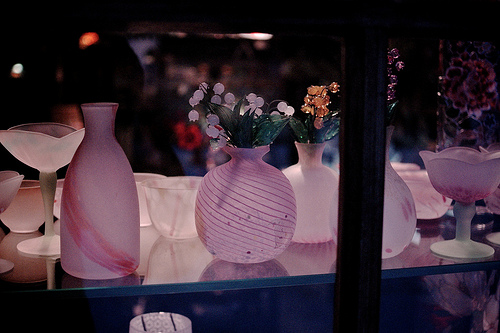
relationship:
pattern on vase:
[224, 198, 289, 234] [193, 140, 293, 271]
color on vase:
[61, 180, 124, 278] [58, 100, 147, 284]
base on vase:
[427, 232, 499, 260] [418, 147, 495, 263]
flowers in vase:
[187, 82, 295, 152] [191, 140, 300, 265]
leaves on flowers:
[240, 117, 269, 142] [196, 79, 296, 117]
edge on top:
[74, 278, 293, 301] [1, 224, 493, 294]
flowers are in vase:
[187, 82, 295, 152] [194, 145, 299, 264]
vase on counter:
[292, 160, 328, 235] [153, 250, 212, 284]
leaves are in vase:
[240, 117, 269, 142] [208, 166, 282, 252]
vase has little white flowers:
[209, 149, 278, 260] [189, 77, 290, 142]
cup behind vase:
[142, 175, 193, 234] [194, 145, 299, 264]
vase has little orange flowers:
[279, 141, 344, 245] [301, 80, 331, 135]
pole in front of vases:
[341, 103, 380, 273] [199, 150, 330, 252]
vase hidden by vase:
[385, 175, 412, 255] [295, 161, 327, 224]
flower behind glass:
[444, 60, 484, 113] [440, 148, 484, 195]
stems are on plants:
[231, 116, 262, 139] [190, 74, 298, 260]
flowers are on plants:
[187, 82, 295, 152] [189, 89, 294, 268]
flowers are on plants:
[294, 78, 333, 129] [283, 84, 340, 161]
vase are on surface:
[194, 145, 299, 264] [170, 241, 215, 274]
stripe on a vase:
[69, 200, 102, 258] [72, 145, 130, 276]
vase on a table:
[72, 109, 137, 279] [145, 235, 202, 281]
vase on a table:
[194, 145, 299, 264] [155, 250, 198, 286]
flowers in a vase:
[182, 80, 286, 142] [211, 160, 289, 259]